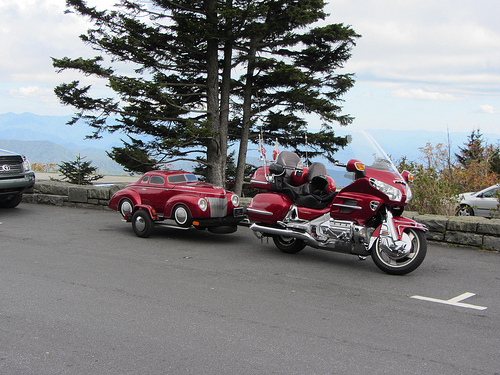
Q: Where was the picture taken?
A: It was taken at the road.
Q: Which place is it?
A: It is a road.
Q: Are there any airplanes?
A: No, there are no airplanes.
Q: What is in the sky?
A: The clouds are in the sky.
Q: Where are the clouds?
A: The clouds are in the sky.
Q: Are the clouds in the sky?
A: Yes, the clouds are in the sky.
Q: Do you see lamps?
A: No, there are no lamps.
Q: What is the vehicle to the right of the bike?
A: The vehicle is a car.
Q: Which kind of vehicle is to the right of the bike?
A: The vehicle is a car.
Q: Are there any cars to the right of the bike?
A: Yes, there is a car to the right of the bike.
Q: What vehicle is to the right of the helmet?
A: The vehicle is a car.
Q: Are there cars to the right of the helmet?
A: Yes, there is a car to the right of the helmet.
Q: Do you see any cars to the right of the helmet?
A: Yes, there is a car to the right of the helmet.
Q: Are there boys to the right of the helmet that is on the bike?
A: No, there is a car to the right of the helmet.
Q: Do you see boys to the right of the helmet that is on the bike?
A: No, there is a car to the right of the helmet.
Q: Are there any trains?
A: No, there are no trains.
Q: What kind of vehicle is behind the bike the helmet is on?
A: The vehicle is a car.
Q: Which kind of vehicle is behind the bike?
A: The vehicle is a car.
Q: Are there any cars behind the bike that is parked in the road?
A: Yes, there is a car behind the bike.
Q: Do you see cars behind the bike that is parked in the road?
A: Yes, there is a car behind the bike.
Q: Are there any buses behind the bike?
A: No, there is a car behind the bike.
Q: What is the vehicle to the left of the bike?
A: The vehicle is a car.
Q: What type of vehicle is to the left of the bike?
A: The vehicle is a car.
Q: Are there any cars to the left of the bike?
A: Yes, there is a car to the left of the bike.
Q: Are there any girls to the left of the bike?
A: No, there is a car to the left of the bike.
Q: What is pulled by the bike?
A: The car is pulled by the bike.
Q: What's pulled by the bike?
A: The car is pulled by the bike.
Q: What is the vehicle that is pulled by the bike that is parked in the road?
A: The vehicle is a car.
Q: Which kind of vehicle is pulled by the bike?
A: The vehicle is a car.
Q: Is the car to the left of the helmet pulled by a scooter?
A: No, the car is pulled by a bike.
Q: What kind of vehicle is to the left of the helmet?
A: The vehicle is a car.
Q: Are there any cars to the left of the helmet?
A: Yes, there is a car to the left of the helmet.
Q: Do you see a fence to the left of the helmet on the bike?
A: No, there is a car to the left of the helmet.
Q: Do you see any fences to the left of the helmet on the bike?
A: No, there is a car to the left of the helmet.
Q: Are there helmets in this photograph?
A: Yes, there is a helmet.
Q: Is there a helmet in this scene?
A: Yes, there is a helmet.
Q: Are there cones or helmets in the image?
A: Yes, there is a helmet.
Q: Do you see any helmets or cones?
A: Yes, there is a helmet.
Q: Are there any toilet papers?
A: No, there are no toilet papers.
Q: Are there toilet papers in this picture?
A: No, there are no toilet papers.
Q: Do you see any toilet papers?
A: No, there are no toilet papers.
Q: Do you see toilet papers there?
A: No, there are no toilet papers.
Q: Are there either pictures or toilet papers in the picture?
A: No, there are no toilet papers or pictures.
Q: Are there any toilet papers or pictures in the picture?
A: No, there are no toilet papers or pictures.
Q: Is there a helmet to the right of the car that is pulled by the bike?
A: Yes, there is a helmet to the right of the car.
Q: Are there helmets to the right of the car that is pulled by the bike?
A: Yes, there is a helmet to the right of the car.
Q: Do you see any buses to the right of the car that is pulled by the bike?
A: No, there is a helmet to the right of the car.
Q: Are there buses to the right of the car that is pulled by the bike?
A: No, there is a helmet to the right of the car.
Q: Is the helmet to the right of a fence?
A: No, the helmet is to the right of a car.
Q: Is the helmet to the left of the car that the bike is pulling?
A: No, the helmet is to the right of the car.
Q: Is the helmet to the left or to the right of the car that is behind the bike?
A: The helmet is to the right of the car.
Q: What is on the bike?
A: The helmet is on the bike.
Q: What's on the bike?
A: The helmet is on the bike.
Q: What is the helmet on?
A: The helmet is on the bike.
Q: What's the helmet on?
A: The helmet is on the bike.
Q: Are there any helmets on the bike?
A: Yes, there is a helmet on the bike.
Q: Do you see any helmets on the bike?
A: Yes, there is a helmet on the bike.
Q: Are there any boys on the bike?
A: No, there is a helmet on the bike.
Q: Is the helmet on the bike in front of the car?
A: Yes, the helmet is on the bike.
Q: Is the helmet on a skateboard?
A: No, the helmet is on the bike.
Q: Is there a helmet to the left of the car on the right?
A: Yes, there is a helmet to the left of the car.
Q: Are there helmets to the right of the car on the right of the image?
A: No, the helmet is to the left of the car.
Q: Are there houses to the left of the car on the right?
A: No, there is a helmet to the left of the car.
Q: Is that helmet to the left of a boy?
A: No, the helmet is to the left of a car.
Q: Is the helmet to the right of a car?
A: No, the helmet is to the left of a car.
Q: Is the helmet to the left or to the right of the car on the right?
A: The helmet is to the left of the car.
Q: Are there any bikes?
A: Yes, there is a bike.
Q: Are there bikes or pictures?
A: Yes, there is a bike.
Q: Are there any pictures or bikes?
A: Yes, there is a bike.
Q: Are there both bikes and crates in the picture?
A: No, there is a bike but no crates.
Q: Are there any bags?
A: No, there are no bags.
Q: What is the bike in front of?
A: The bike is in front of the car.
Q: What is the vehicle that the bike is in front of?
A: The vehicle is a car.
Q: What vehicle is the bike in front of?
A: The bike is in front of the car.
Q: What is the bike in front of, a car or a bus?
A: The bike is in front of a car.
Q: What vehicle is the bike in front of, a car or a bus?
A: The bike is in front of a car.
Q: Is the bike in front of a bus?
A: No, the bike is in front of the car.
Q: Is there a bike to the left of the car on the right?
A: Yes, there is a bike to the left of the car.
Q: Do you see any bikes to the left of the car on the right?
A: Yes, there is a bike to the left of the car.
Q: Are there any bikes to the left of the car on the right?
A: Yes, there is a bike to the left of the car.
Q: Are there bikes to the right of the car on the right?
A: No, the bike is to the left of the car.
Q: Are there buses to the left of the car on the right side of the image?
A: No, there is a bike to the left of the car.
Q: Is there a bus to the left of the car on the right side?
A: No, there is a bike to the left of the car.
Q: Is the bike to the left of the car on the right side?
A: Yes, the bike is to the left of the car.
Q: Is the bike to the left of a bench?
A: No, the bike is to the left of the car.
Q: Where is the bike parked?
A: The bike is parked in the road.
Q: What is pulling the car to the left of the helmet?
A: The bike is pulling the car.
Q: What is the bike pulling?
A: The bike is pulling the car.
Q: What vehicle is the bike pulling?
A: The bike is pulling the car.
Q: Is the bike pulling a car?
A: Yes, the bike is pulling a car.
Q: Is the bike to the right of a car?
A: Yes, the bike is to the right of a car.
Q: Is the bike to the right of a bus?
A: No, the bike is to the right of a car.